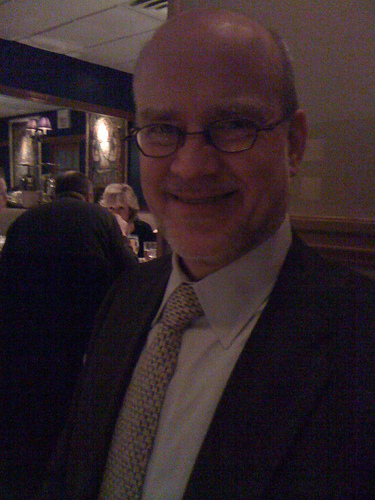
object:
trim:
[282, 218, 373, 248]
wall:
[263, 7, 372, 235]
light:
[39, 115, 54, 134]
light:
[22, 117, 40, 131]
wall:
[14, 115, 85, 133]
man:
[5, 167, 145, 382]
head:
[130, 5, 306, 258]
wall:
[4, 114, 136, 201]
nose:
[165, 144, 225, 189]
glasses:
[120, 114, 267, 158]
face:
[135, 106, 289, 260]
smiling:
[161, 185, 239, 212]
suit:
[50, 213, 373, 498]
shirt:
[90, 213, 305, 497]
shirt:
[2, 195, 140, 358]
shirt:
[108, 215, 155, 262]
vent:
[123, 2, 186, 30]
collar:
[149, 242, 279, 348]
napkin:
[112, 212, 129, 237]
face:
[103, 200, 129, 220]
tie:
[87, 283, 202, 494]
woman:
[94, 181, 154, 256]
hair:
[95, 181, 140, 218]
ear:
[279, 100, 320, 171]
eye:
[146, 119, 182, 148]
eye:
[214, 116, 252, 137]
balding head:
[127, 5, 301, 125]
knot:
[152, 277, 209, 329]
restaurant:
[5, 6, 373, 497]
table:
[124, 241, 158, 267]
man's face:
[125, 7, 305, 260]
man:
[36, 6, 373, 497]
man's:
[123, 27, 313, 262]